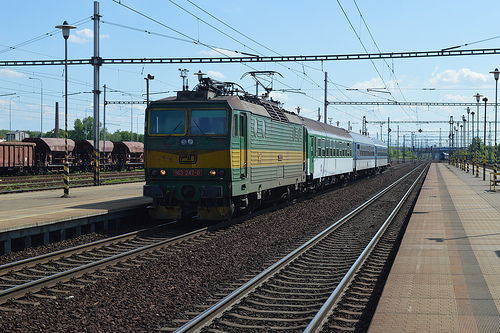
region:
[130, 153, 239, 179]
two yellow train lights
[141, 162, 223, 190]
two yellow train lights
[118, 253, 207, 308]
pebbles on the train tracks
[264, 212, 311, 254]
pebbles on the train tracks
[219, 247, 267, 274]
pebbles on the train tracks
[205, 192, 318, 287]
pebbles on the train tracks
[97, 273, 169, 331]
pebbles on the train tracks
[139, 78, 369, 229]
the train is green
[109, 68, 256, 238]
the train is green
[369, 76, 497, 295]
the platform is empty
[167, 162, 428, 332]
Tracks beside the train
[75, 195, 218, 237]
A shadow on the ground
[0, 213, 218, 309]
Tracks in front of the train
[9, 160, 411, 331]
Gravel next to the train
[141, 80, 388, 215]
A train on the tracks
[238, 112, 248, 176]
A door on the train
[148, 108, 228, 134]
A window on the train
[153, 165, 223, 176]
Headlights on the train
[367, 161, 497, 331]
A platform near the tracks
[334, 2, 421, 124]
Wires above the train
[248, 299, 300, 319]
crosstie on the track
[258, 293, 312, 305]
crosstie on the track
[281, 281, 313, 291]
crosstie on the track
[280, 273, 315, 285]
crosstie on the track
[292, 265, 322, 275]
crosstie on the track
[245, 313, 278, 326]
crosstie on the track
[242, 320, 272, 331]
crosstie on the track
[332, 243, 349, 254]
crosstie on the track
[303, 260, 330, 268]
crosstie on the track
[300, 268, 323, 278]
crosstie on the track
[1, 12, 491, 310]
The train is traveling through a city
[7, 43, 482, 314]
The train is on the railroad tracks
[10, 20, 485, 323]
The train is pulling several cars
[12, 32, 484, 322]
The train is bringing people home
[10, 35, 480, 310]
A train is carrying city commuters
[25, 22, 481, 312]
The train is owned by the city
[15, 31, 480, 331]
The train has a powerful motor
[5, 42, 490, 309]
The train is running on time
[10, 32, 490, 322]
The train is approaching a stop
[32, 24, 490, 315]
The train is running in daytime